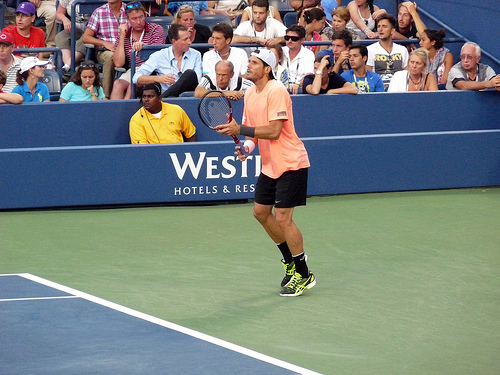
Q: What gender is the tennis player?
A: Male.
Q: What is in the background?
A: Group of fans.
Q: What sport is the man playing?
A: Tennis.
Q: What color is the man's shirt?
A: Orange.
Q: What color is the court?
A: Blue white and green.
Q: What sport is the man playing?
A: Tennis.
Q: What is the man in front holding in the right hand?
A: Tennis racket.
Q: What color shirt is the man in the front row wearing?
A: Yellow.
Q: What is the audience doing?
A: Watching the tennis match.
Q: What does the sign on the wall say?
A: Westin Hotels & Resorts.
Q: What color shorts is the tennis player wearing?
A: Black.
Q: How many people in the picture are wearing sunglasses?
A: 1.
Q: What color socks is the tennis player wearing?
A: Black.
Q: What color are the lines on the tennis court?
A: White.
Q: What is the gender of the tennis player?
A: Male.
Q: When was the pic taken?
A: During the day.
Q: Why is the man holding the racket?
A: To hit the ball.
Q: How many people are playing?
A: 1.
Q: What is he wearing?
A: Sneakers.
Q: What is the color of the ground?
A: Green and blue.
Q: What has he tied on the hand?
A: Band.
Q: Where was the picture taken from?
A: Tennis court.